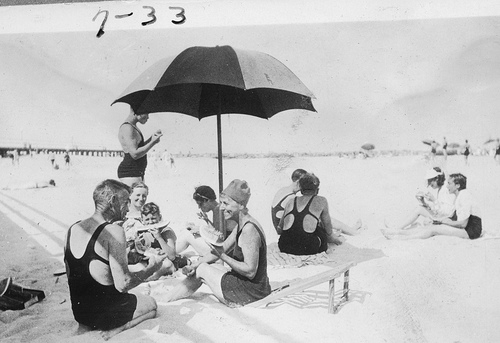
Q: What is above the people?
A: Umbrella.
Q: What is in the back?
A: Sky.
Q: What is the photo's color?
A: White and black.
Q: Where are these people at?
A: Beach.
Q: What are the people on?
A: Sand.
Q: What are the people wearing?
A: Swimsuits.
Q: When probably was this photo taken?
A: 1933.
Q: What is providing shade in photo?
A: Umbrella.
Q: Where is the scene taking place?
A: Beach.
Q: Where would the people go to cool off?
A: To water.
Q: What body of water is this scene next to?
A: Ocean.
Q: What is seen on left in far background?
A: Pier.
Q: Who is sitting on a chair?
A: Two ladies.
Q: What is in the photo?
A: An umbrella.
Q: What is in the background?
A: The sky.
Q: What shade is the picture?
A: Black and white.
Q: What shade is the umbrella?
A: Two colors.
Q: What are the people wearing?
A: Bathing suits.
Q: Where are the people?
A: On the beach.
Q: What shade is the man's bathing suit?
A: Black.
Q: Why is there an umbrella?
A: Shade.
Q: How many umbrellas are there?
A: One.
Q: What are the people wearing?
A: Bathing suits.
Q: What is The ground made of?
A: Sand.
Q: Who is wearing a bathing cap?
A: A woman.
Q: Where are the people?
A: Beach.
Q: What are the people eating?
A: Watermelon.